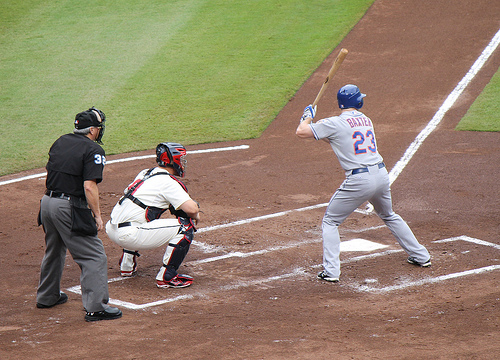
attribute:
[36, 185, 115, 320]
gray pants — grey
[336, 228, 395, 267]
white base — here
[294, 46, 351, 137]
bat — brown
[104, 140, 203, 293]
catcher — squatted down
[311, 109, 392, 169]
gray jersey — grey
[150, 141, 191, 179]
mask — grey, red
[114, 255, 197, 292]
shoes — red, white